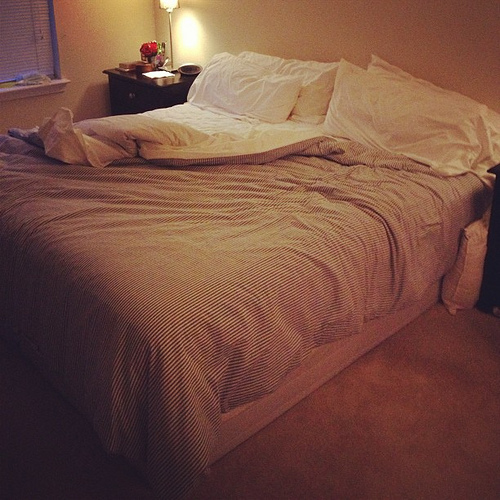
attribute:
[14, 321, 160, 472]
wall — bad sentence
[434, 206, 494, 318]
pillow — white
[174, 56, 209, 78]
clock — oval, alarm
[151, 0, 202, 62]
light — on 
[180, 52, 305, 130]
pillow — white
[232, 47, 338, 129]
pillow — white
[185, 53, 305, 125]
pillow — white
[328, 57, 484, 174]
pillow — white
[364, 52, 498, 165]
pillow — white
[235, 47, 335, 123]
pillow — white